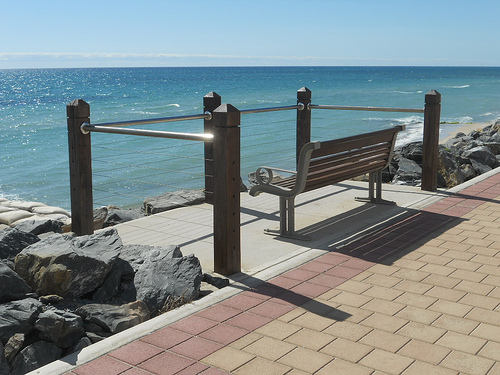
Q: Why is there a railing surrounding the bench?
A: To ensure people do not fall.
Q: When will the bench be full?
A: When people sit on it.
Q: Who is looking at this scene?
A: The photographer.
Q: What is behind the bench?
A: Its shadow.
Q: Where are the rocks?
A: On either side of the slab with the bench on it.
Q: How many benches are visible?
A: One.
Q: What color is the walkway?
A: Red.